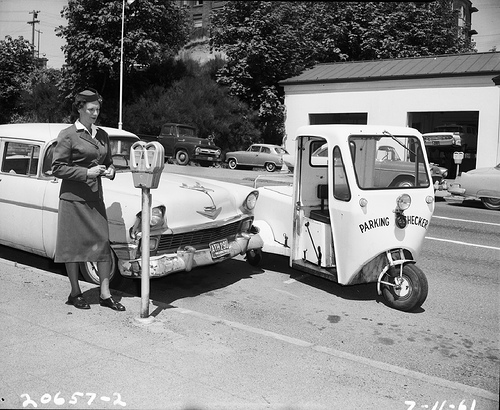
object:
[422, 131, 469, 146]
car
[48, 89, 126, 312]
clerk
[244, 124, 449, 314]
cart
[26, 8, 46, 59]
pole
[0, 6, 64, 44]
wires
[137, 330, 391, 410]
asphalt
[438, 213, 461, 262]
ground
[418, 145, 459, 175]
lift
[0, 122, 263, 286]
car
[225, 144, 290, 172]
car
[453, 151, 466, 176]
meter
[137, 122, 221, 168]
cars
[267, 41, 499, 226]
business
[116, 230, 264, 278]
bumper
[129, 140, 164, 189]
meter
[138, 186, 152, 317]
pole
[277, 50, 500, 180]
building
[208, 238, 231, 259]
license plate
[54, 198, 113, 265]
skirt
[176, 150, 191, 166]
white tire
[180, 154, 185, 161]
hub cap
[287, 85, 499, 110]
wall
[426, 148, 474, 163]
car lift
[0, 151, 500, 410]
street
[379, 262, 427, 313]
wheel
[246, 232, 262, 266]
wheel